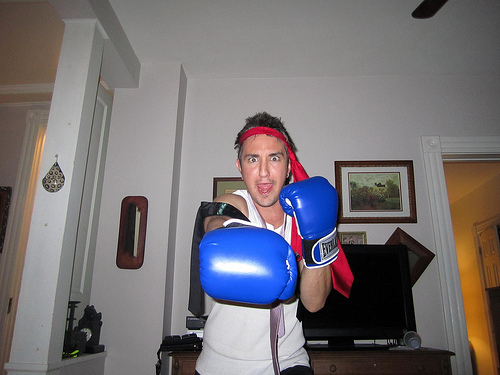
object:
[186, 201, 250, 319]
tie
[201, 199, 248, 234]
arm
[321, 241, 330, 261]
letters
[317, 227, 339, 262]
label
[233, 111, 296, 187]
hair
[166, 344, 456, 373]
table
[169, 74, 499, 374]
wall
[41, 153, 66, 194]
item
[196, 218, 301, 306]
boxing gear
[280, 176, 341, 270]
boxing gear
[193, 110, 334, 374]
man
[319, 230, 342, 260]
writing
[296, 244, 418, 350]
television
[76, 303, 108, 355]
clock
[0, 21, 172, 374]
corner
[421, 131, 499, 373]
doorway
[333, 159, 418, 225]
picture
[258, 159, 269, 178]
nose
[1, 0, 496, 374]
room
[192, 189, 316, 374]
body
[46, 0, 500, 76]
wall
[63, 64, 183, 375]
wall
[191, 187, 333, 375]
tank top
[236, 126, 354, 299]
red tie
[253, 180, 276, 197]
mouth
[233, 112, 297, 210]
head